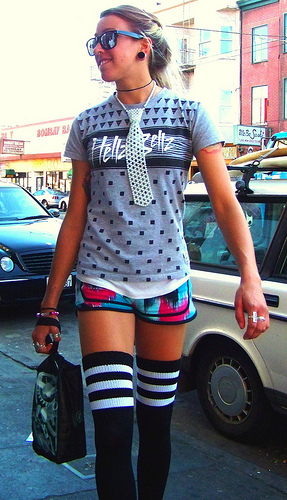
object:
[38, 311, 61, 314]
bracelet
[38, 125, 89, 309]
arm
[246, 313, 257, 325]
ring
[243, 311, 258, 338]
finger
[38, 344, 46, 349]
ring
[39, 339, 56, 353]
finger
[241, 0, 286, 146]
building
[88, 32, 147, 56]
sunglasses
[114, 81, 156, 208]
tie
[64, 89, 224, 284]
shirt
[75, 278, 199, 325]
shorts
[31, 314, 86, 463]
bag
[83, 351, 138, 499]
stocking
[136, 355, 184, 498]
stocking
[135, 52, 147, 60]
earring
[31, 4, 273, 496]
woman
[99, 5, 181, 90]
hair